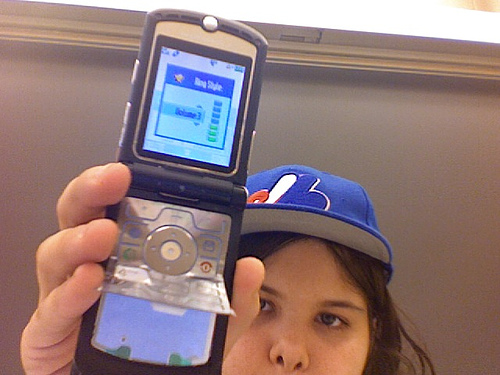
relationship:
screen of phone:
[142, 44, 247, 168] [72, 7, 268, 374]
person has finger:
[19, 164, 437, 373] [57, 160, 132, 232]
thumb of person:
[224, 256, 267, 359] [19, 164, 437, 373]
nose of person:
[268, 336, 311, 373] [19, 164, 437, 373]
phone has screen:
[72, 7, 268, 374] [142, 44, 247, 168]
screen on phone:
[142, 44, 247, 168] [72, 7, 268, 374]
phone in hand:
[72, 7, 268, 374] [19, 163, 267, 373]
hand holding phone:
[19, 163, 267, 373] [72, 7, 268, 374]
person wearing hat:
[19, 164, 437, 373] [241, 163, 392, 285]